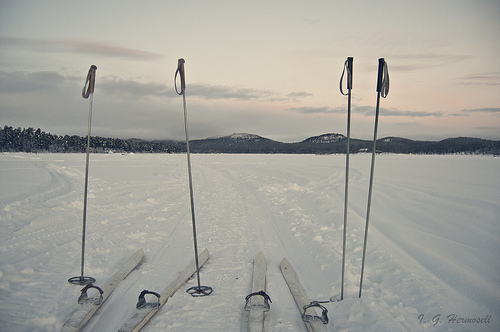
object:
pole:
[165, 52, 223, 301]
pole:
[334, 55, 358, 306]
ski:
[51, 243, 149, 331]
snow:
[197, 155, 340, 248]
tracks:
[12, 151, 339, 330]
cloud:
[99, 65, 172, 105]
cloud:
[188, 80, 312, 108]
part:
[175, 1, 462, 36]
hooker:
[338, 54, 359, 97]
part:
[107, 159, 178, 217]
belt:
[78, 62, 100, 99]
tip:
[110, 247, 151, 278]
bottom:
[183, 282, 216, 298]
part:
[205, 127, 290, 153]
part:
[213, 74, 338, 123]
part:
[9, 124, 76, 156]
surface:
[206, 166, 339, 224]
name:
[414, 311, 497, 328]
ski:
[117, 243, 213, 331]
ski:
[241, 248, 273, 331]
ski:
[274, 255, 332, 331]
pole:
[67, 63, 102, 295]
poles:
[357, 56, 391, 299]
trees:
[0, 125, 85, 153]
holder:
[172, 57, 191, 101]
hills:
[420, 135, 497, 156]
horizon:
[302, 130, 499, 137]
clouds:
[4, 69, 67, 99]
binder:
[132, 287, 164, 309]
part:
[335, 77, 356, 99]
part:
[14, 192, 77, 239]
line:
[0, 152, 80, 269]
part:
[367, 256, 419, 331]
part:
[417, 314, 454, 330]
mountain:
[193, 130, 345, 153]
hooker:
[372, 56, 397, 99]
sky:
[0, 0, 500, 57]